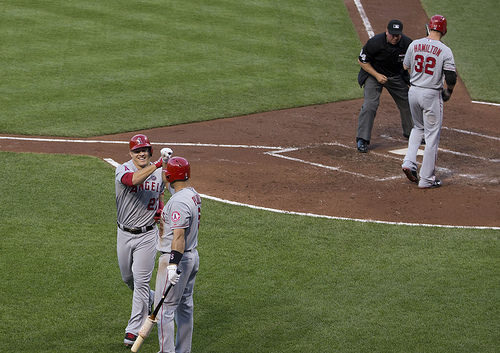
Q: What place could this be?
A: It is a field.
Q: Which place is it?
A: It is a field.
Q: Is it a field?
A: Yes, it is a field.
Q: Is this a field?
A: Yes, it is a field.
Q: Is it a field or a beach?
A: It is a field.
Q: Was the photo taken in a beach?
A: No, the picture was taken in a field.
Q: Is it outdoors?
A: Yes, it is outdoors.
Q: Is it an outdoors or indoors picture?
A: It is outdoors.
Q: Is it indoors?
A: No, it is outdoors.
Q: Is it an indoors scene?
A: No, it is outdoors.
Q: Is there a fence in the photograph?
A: No, there are no fences.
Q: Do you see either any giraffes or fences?
A: No, there are no fences or giraffes.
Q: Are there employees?
A: No, there are no employees.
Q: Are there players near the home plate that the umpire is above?
A: Yes, there is a player near the home plate.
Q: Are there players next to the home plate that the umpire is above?
A: Yes, there is a player next to the home plate.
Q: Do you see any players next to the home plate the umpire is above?
A: Yes, there is a player next to the home plate.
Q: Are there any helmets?
A: Yes, there is a helmet.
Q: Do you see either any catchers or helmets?
A: Yes, there is a helmet.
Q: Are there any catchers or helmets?
A: Yes, there is a helmet.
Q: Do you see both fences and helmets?
A: No, there is a helmet but no fences.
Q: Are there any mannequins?
A: No, there are no mannequins.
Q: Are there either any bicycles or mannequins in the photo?
A: No, there are no mannequins or bicycles.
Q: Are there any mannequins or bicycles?
A: No, there are no mannequins or bicycles.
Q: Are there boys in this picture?
A: No, there are no boys.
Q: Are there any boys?
A: No, there are no boys.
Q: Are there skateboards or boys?
A: No, there are no boys or skateboards.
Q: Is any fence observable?
A: No, there are no fences.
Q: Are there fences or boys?
A: No, there are no fences or boys.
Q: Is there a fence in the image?
A: No, there are no fences.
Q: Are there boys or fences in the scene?
A: No, there are no fences or boys.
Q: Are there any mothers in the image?
A: No, there are no mothers.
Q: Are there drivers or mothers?
A: No, there are no mothers or drivers.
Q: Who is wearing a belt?
A: The man is wearing a belt.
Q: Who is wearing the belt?
A: The man is wearing a belt.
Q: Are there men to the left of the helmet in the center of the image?
A: Yes, there is a man to the left of the helmet.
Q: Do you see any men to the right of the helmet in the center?
A: No, the man is to the left of the helmet.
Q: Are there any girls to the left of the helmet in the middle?
A: No, there is a man to the left of the helmet.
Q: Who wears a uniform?
A: The man wears a uniform.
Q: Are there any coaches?
A: No, there are no coaches.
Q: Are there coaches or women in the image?
A: No, there are no coaches or women.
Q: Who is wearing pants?
A: The man is wearing pants.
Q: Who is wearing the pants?
A: The man is wearing pants.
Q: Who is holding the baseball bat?
A: The man is holding the baseball bat.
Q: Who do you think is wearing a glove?
A: The man is wearing a glove.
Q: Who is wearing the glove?
A: The man is wearing a glove.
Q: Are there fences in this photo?
A: No, there are no fences.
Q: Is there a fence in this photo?
A: No, there are no fences.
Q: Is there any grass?
A: Yes, there is grass.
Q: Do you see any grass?
A: Yes, there is grass.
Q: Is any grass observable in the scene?
A: Yes, there is grass.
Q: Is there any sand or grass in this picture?
A: Yes, there is grass.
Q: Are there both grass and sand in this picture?
A: No, there is grass but no sand.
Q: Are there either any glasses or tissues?
A: No, there are no glasses or tissues.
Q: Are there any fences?
A: No, there are no fences.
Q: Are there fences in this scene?
A: No, there are no fences.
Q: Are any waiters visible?
A: No, there are no waiters.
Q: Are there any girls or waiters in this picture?
A: No, there are no waiters or girls.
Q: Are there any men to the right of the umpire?
A: Yes, there is a man to the right of the umpire.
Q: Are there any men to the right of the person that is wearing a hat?
A: Yes, there is a man to the right of the umpire.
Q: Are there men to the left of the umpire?
A: No, the man is to the right of the umpire.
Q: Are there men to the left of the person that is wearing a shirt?
A: No, the man is to the right of the umpire.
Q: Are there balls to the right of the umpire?
A: No, there is a man to the right of the umpire.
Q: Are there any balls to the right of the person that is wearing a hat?
A: No, there is a man to the right of the umpire.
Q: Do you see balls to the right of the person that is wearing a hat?
A: No, there is a man to the right of the umpire.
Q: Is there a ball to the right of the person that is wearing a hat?
A: No, there is a man to the right of the umpire.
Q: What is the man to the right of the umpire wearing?
A: The man is wearing a uniform.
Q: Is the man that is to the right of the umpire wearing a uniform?
A: Yes, the man is wearing a uniform.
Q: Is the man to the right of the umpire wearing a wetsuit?
A: No, the man is wearing a uniform.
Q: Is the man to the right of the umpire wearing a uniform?
A: Yes, the man is wearing a uniform.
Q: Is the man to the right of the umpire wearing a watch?
A: No, the man is wearing a uniform.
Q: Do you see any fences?
A: No, there are no fences.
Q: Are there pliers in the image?
A: No, there are no pliers.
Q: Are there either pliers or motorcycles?
A: No, there are no pliers or motorcycles.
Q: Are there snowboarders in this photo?
A: No, there are no snowboarders.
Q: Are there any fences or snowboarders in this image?
A: No, there are no snowboarders or fences.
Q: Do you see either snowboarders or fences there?
A: No, there are no snowboarders or fences.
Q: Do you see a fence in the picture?
A: No, there are no fences.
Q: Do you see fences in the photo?
A: No, there are no fences.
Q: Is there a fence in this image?
A: No, there are no fences.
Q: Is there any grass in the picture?
A: Yes, there is grass.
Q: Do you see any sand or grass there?
A: Yes, there is grass.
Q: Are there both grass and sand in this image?
A: No, there is grass but no sand.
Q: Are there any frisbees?
A: No, there are no frisbees.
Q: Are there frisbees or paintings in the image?
A: No, there are no frisbees or paintings.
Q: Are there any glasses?
A: No, there are no glasses.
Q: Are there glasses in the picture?
A: No, there are no glasses.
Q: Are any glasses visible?
A: No, there are no glasses.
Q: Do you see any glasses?
A: No, there are no glasses.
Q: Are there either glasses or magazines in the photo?
A: No, there are no glasses or magazines.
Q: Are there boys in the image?
A: No, there are no boys.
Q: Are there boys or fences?
A: No, there are no boys or fences.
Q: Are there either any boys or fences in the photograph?
A: No, there are no fences or boys.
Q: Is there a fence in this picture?
A: No, there are no fences.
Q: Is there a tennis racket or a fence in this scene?
A: No, there are no fences or rackets.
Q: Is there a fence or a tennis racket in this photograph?
A: No, there are no fences or rackets.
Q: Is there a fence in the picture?
A: No, there are no fences.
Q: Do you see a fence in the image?
A: No, there are no fences.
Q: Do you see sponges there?
A: No, there are no sponges.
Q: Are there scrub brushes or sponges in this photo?
A: No, there are no sponges or scrub brushes.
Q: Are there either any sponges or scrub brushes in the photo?
A: No, there are no sponges or scrub brushes.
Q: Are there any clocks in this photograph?
A: No, there are no clocks.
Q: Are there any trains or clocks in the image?
A: No, there are no clocks or trains.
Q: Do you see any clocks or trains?
A: No, there are no clocks or trains.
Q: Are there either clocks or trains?
A: No, there are no clocks or trains.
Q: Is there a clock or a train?
A: No, there are no clocks or trains.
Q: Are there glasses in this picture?
A: No, there are no glasses.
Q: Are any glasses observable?
A: No, there are no glasses.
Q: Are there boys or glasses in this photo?
A: No, there are no glasses or boys.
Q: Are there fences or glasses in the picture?
A: No, there are no glasses or fences.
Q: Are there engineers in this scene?
A: No, there are no engineers.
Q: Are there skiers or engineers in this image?
A: No, there are no engineers or skiers.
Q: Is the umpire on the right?
A: Yes, the umpire is on the right of the image.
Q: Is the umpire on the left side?
A: No, the umpire is on the right of the image.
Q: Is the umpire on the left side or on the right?
A: The umpire is on the right of the image.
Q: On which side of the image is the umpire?
A: The umpire is on the right of the image.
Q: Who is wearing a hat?
A: The umpire is wearing a hat.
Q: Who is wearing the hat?
A: The umpire is wearing a hat.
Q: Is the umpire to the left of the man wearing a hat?
A: Yes, the umpire is wearing a hat.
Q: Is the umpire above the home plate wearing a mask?
A: No, the umpire is wearing a hat.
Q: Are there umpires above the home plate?
A: Yes, there is an umpire above the home plate.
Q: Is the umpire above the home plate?
A: Yes, the umpire is above the home plate.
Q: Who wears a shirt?
A: The umpire wears a shirt.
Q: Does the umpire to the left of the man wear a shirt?
A: Yes, the umpire wears a shirt.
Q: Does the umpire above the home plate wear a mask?
A: No, the umpire wears a shirt.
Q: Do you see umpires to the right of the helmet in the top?
A: No, the umpire is to the left of the helmet.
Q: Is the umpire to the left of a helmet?
A: Yes, the umpire is to the left of a helmet.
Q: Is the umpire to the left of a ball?
A: No, the umpire is to the left of a helmet.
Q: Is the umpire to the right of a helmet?
A: No, the umpire is to the left of a helmet.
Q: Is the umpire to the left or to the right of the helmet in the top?
A: The umpire is to the left of the helmet.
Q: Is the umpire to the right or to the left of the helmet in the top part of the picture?
A: The umpire is to the left of the helmet.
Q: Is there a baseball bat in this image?
A: Yes, there is a baseball bat.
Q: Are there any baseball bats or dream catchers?
A: Yes, there is a baseball bat.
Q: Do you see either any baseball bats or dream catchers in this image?
A: Yes, there is a baseball bat.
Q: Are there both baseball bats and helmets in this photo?
A: Yes, there are both a baseball bat and a helmet.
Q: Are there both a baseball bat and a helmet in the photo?
A: Yes, there are both a baseball bat and a helmet.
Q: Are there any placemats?
A: No, there are no placemats.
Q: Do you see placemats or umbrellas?
A: No, there are no placemats or umbrellas.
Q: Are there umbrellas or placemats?
A: No, there are no placemats or umbrellas.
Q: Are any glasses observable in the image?
A: No, there are no glasses.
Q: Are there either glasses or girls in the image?
A: No, there are no glasses or girls.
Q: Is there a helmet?
A: Yes, there is a helmet.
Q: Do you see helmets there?
A: Yes, there is a helmet.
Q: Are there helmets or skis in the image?
A: Yes, there is a helmet.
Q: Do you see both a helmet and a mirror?
A: No, there is a helmet but no mirrors.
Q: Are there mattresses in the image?
A: No, there are no mattresses.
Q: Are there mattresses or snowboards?
A: No, there are no mattresses or snowboards.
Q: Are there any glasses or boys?
A: No, there are no glasses or boys.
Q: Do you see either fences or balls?
A: No, there are no fences or balls.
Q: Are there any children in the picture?
A: No, there are no children.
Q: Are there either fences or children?
A: No, there are no children or fences.